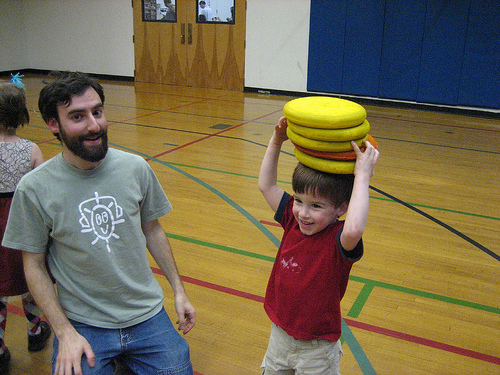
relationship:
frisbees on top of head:
[282, 93, 379, 174] [290, 160, 353, 235]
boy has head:
[255, 115, 379, 374] [290, 160, 353, 235]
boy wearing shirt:
[255, 115, 379, 374] [262, 190, 365, 341]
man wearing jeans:
[2, 68, 197, 373] [53, 304, 195, 373]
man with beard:
[2, 68, 197, 373] [55, 120, 109, 162]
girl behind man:
[1, 70, 50, 362] [2, 68, 197, 373]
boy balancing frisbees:
[255, 115, 379, 374] [282, 93, 379, 174]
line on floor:
[20, 131, 499, 222] [1, 72, 499, 374]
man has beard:
[2, 68, 197, 373] [55, 120, 109, 162]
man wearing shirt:
[2, 68, 197, 373] [2, 146, 172, 329]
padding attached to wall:
[305, 1, 499, 110] [24, 1, 499, 113]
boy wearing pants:
[255, 115, 379, 374] [262, 321, 344, 374]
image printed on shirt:
[78, 189, 126, 252] [2, 146, 172, 329]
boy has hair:
[255, 115, 379, 374] [292, 161, 355, 209]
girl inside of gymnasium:
[1, 70, 50, 362] [1, 1, 499, 374]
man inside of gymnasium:
[2, 68, 197, 373] [1, 1, 499, 374]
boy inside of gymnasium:
[255, 115, 379, 374] [1, 1, 499, 374]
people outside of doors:
[158, 0, 233, 23] [132, 1, 246, 92]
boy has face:
[255, 115, 379, 374] [290, 188, 327, 235]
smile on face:
[297, 215, 315, 229] [290, 188, 327, 235]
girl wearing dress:
[1, 70, 50, 362] [1, 137, 57, 298]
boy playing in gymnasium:
[255, 115, 379, 374] [1, 1, 499, 374]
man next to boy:
[2, 68, 197, 373] [255, 115, 379, 374]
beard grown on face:
[55, 120, 109, 162] [60, 88, 108, 160]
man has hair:
[2, 68, 197, 373] [36, 68, 105, 143]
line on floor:
[146, 262, 498, 364] [1, 72, 499, 374]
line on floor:
[135, 107, 285, 160] [1, 72, 499, 374]